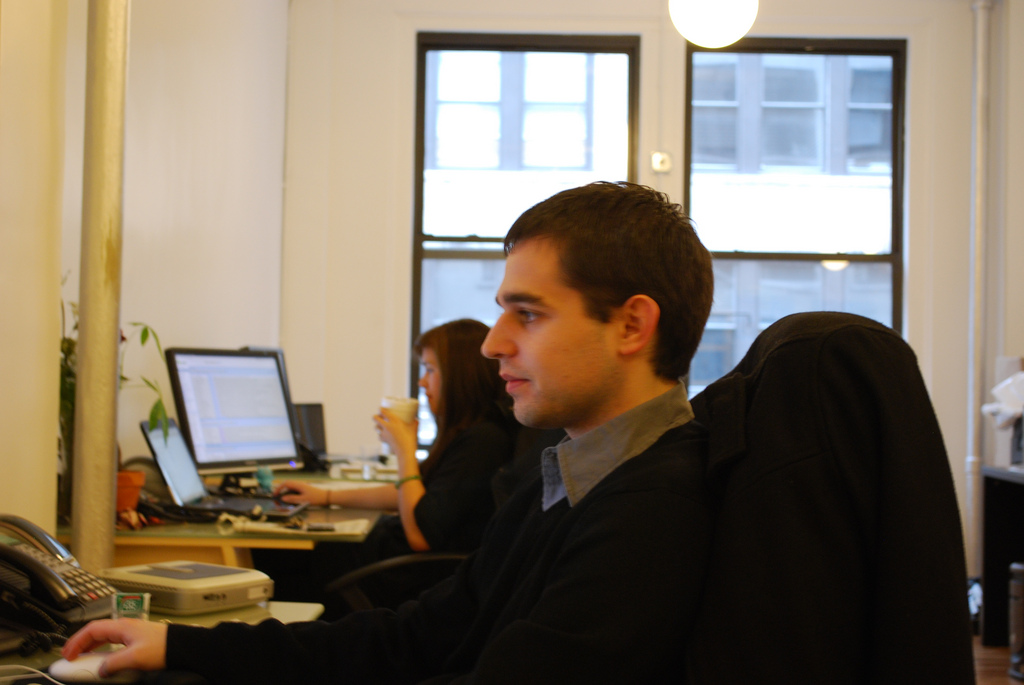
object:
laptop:
[139, 418, 311, 517]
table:
[55, 472, 398, 566]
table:
[0, 600, 323, 685]